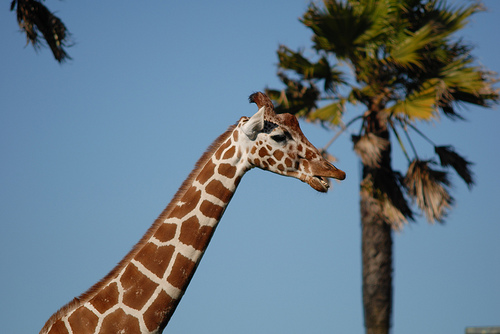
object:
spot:
[90, 282, 124, 312]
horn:
[246, 90, 276, 113]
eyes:
[268, 132, 287, 146]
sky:
[0, 0, 500, 334]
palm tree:
[253, 0, 495, 334]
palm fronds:
[376, 73, 454, 129]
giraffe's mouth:
[310, 168, 350, 195]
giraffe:
[37, 90, 349, 333]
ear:
[242, 104, 267, 135]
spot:
[215, 160, 241, 181]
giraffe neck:
[37, 157, 254, 333]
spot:
[168, 254, 199, 291]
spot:
[178, 213, 202, 250]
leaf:
[9, 0, 77, 64]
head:
[242, 87, 348, 194]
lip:
[316, 168, 349, 181]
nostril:
[321, 160, 340, 171]